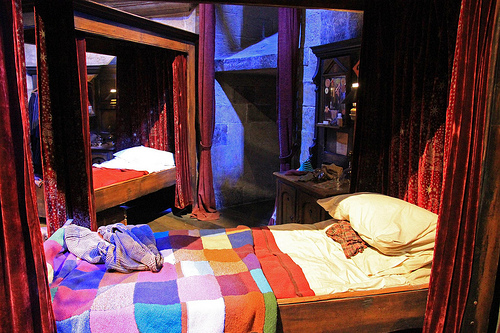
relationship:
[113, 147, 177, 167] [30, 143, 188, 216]
pillow on top of bed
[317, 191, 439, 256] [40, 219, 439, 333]
pillow on top of bed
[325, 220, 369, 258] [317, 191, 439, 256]
cloth next to a pillow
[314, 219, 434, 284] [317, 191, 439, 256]
pillow under top pillow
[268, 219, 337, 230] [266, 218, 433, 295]
shadow on top of a sheet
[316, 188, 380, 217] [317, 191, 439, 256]
shadow on top of pillow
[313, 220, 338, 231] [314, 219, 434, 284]
shadow on top of a pillow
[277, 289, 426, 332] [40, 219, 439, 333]
wood side of a bed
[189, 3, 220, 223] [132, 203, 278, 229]
drape touching floor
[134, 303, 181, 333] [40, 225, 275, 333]
square on bedspread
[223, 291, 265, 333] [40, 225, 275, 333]
square on a bedspread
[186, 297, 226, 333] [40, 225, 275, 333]
square on a bedspread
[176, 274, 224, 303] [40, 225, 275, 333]
square on a bedspread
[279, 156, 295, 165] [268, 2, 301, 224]
band around a drape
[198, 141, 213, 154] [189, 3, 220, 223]
band around a drape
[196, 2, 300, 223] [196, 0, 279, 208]
entrance way made of concrete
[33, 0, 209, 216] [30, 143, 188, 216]
alcove that has a bed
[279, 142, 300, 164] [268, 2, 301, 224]
band tied on curtain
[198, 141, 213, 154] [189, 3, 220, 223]
sash tied on curtain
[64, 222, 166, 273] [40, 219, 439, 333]
robe on top of bed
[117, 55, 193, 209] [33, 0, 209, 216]
curtain inside of bed frame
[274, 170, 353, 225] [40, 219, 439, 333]
nightstand near bed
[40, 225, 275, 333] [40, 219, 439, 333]
blanket on top of bed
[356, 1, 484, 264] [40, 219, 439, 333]
curtain behind bed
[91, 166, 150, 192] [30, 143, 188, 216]
blanket on bed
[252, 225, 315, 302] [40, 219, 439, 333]
blanket on bed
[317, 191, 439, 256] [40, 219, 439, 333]
pillow on top of a bed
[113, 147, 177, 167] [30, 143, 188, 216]
pillow on top of a bed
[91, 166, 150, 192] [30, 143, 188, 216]
blanket on top of bed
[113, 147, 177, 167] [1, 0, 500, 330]
pillow inside of room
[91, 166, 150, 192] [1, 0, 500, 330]
blanket inside of room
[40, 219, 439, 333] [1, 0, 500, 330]
bed inside of room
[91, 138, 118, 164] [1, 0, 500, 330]
table inside room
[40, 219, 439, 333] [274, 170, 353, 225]
bed next to a table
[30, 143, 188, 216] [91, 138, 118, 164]
bed next to a table